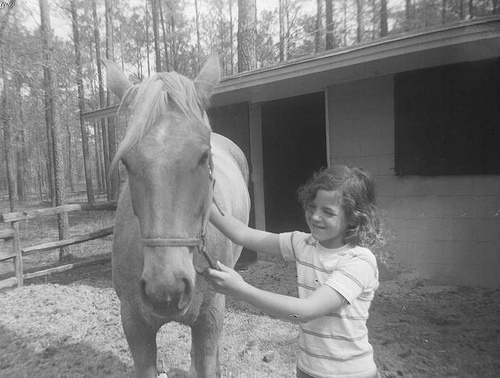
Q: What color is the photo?
A: Black and white.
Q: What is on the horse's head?
A: A bit.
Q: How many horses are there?
A: One.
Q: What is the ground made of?
A: Dirt.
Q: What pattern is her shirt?
A: Striped.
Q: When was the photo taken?
A: Daytime.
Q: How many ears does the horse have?
A: Two.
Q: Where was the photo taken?
A: A horse stable.